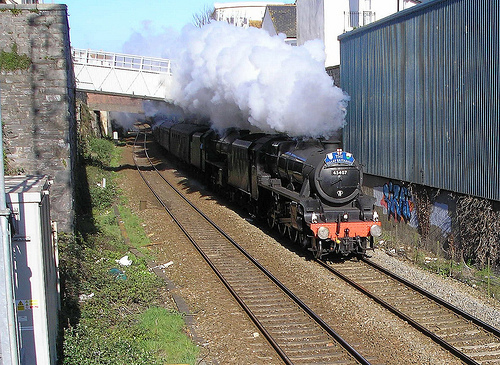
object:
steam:
[135, 19, 350, 139]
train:
[147, 112, 382, 260]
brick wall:
[3, 5, 79, 229]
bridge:
[71, 47, 189, 99]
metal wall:
[342, 20, 499, 192]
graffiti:
[379, 179, 414, 222]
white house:
[290, 1, 396, 69]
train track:
[132, 139, 494, 363]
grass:
[78, 138, 156, 361]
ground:
[90, 135, 217, 349]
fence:
[0, 7, 93, 216]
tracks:
[201, 251, 492, 363]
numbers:
[331, 166, 347, 178]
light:
[318, 227, 331, 238]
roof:
[258, 3, 297, 41]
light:
[366, 224, 385, 239]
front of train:
[321, 223, 378, 238]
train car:
[305, 149, 382, 257]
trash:
[100, 249, 136, 286]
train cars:
[155, 124, 276, 206]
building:
[206, 0, 411, 69]